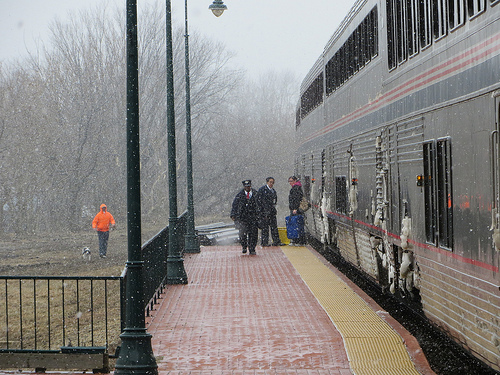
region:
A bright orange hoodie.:
[89, 197, 118, 232]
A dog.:
[74, 238, 98, 263]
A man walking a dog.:
[66, 197, 121, 262]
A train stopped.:
[291, 2, 498, 373]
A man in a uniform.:
[229, 177, 263, 254]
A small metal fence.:
[1, 209, 193, 357]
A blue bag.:
[286, 214, 306, 239]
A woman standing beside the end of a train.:
[278, 171, 317, 251]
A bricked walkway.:
[144, 220, 345, 373]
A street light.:
[164, 0, 241, 284]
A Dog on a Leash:
[68, 223, 100, 270]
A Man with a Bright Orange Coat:
[93, 200, 116, 232]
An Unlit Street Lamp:
[194, 1, 267, 32]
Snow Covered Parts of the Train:
[371, 10, 430, 310]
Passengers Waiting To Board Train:
[254, 170, 312, 251]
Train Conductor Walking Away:
[225, 175, 267, 270]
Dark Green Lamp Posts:
[120, 1, 205, 372]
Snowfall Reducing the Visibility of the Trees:
[192, 18, 292, 175]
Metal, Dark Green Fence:
[0, 267, 120, 352]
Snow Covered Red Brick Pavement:
[200, 260, 306, 373]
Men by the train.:
[226, 146, 385, 308]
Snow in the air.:
[114, 106, 285, 273]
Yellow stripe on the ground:
[290, 226, 379, 340]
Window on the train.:
[402, 129, 459, 254]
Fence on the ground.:
[29, 264, 214, 355]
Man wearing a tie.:
[219, 151, 288, 250]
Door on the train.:
[355, 135, 440, 284]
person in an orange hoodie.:
[55, 175, 140, 295]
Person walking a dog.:
[63, 172, 153, 278]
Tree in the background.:
[44, 118, 186, 273]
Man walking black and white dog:
[91, 200, 119, 256]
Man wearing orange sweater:
[88, 200, 114, 257]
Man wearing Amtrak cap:
[227, 172, 268, 261]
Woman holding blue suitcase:
[281, 170, 307, 244]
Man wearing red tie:
[228, 171, 265, 256]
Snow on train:
[392, 204, 416, 249]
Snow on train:
[317, 195, 332, 240]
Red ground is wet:
[145, 235, 434, 374]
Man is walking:
[230, 178, 271, 257]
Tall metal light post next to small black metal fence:
[111, 0, 158, 374]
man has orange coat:
[93, 214, 122, 244]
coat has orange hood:
[75, 197, 112, 256]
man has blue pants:
[89, 223, 112, 254]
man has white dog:
[82, 243, 99, 263]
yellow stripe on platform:
[270, 250, 385, 370]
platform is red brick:
[198, 236, 325, 362]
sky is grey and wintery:
[212, 18, 309, 75]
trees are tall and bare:
[21, 22, 107, 164]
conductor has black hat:
[233, 171, 256, 233]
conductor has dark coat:
[230, 186, 257, 219]